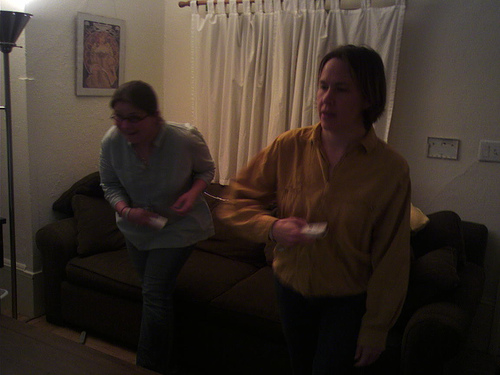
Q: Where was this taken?
A: Living room.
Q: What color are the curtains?
A: White.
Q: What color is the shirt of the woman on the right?
A: Yellow.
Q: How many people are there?
A: 2.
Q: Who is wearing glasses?
A: Woman on the left.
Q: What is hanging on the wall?
A: Pictures.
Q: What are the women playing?
A: Wii.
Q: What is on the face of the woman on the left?
A: Glasses.